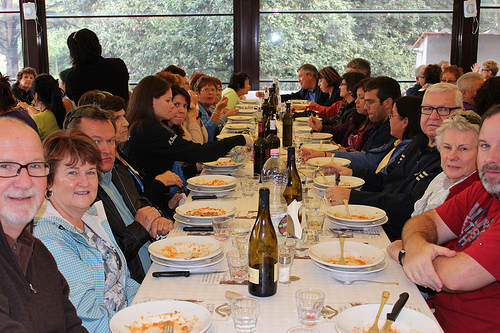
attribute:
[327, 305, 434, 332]
plates — white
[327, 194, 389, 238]
plates — white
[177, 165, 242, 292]
plates — white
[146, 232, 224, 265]
plate — white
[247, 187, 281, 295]
wine — in bottle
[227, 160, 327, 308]
table — large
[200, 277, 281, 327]
glass — small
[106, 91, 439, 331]
table — white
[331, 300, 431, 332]
plates — aligned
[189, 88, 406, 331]
plates — white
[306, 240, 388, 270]
plate — white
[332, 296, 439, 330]
plate — white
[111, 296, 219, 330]
plate — white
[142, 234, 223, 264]
plate — white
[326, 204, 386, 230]
plate — white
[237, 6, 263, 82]
trim — brown